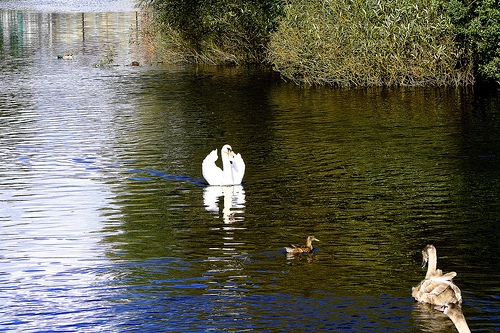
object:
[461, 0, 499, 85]
trees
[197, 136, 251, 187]
swan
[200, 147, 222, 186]
wing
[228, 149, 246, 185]
wing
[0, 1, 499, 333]
river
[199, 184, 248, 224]
reflection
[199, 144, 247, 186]
birds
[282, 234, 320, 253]
birds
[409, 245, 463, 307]
birds